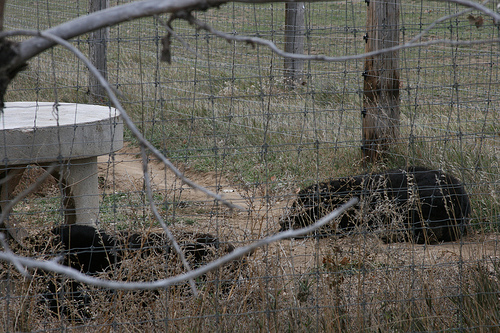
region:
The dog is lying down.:
[260, 141, 484, 259]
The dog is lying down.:
[0, 203, 257, 332]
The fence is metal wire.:
[4, 0, 496, 331]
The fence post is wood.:
[277, 0, 314, 136]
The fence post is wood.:
[85, 0, 113, 145]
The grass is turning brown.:
[3, 1, 497, 331]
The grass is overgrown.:
[4, 4, 499, 331]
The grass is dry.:
[3, 0, 499, 331]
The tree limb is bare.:
[1, 178, 378, 303]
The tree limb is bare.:
[153, 0, 498, 74]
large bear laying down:
[279, 156, 460, 249]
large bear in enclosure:
[262, 150, 478, 245]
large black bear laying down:
[273, 152, 470, 259]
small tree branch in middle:
[119, 195, 351, 289]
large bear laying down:
[7, 206, 240, 296]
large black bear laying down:
[0, 208, 250, 329]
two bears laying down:
[3, 163, 482, 325]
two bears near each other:
[43, 153, 488, 325]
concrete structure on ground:
[0, 96, 137, 196]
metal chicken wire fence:
[85, 23, 411, 203]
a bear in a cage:
[270, 165, 478, 237]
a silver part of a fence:
[205, 92, 297, 166]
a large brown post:
[347, 58, 401, 110]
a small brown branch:
[95, 9, 159, 31]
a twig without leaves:
[127, 86, 198, 186]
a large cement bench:
[34, 101, 128, 191]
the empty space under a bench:
[4, 165, 74, 233]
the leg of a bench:
[38, 161, 103, 223]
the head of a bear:
[264, 173, 321, 225]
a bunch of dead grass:
[287, 253, 375, 308]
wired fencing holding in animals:
[206, 58, 366, 152]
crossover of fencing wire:
[262, 140, 268, 151]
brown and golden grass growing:
[335, 271, 459, 318]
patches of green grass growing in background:
[416, 48, 464, 76]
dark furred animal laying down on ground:
[283, 167, 466, 240]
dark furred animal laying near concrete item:
[26, 221, 244, 278]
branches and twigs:
[0, 16, 126, 69]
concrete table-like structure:
[3, 96, 107, 223]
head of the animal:
[283, 178, 330, 225]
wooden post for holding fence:
[363, 0, 400, 154]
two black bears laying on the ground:
[0, 165, 470, 325]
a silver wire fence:
[3, 2, 498, 331]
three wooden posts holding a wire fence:
[85, 0, 398, 169]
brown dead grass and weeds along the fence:
[3, 154, 498, 329]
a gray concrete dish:
[3, 100, 123, 257]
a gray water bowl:
[1, 99, 123, 255]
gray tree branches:
[0, 0, 499, 300]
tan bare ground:
[99, 155, 484, 267]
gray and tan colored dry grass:
[3, 0, 498, 187]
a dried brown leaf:
[463, 12, 489, 29]